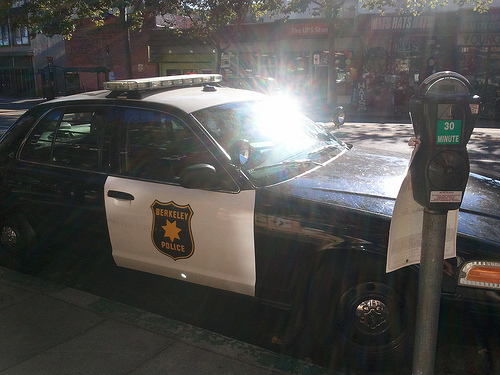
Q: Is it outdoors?
A: Yes, it is outdoors.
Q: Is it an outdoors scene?
A: Yes, it is outdoors.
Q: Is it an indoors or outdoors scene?
A: It is outdoors.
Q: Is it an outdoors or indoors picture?
A: It is outdoors.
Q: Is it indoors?
A: No, it is outdoors.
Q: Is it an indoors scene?
A: No, it is outdoors.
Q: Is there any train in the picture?
A: No, there are no trains.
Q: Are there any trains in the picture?
A: No, there are no trains.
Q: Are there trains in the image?
A: No, there are no trains.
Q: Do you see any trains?
A: No, there are no trains.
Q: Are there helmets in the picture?
A: No, there are no helmets.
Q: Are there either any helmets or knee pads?
A: No, there are no helmets or knee pads.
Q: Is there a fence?
A: No, there are no fences.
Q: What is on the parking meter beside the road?
A: The sign is on the parking meter.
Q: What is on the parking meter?
A: The sign is on the parking meter.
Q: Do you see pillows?
A: No, there are no pillows.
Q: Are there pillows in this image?
A: No, there are no pillows.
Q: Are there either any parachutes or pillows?
A: No, there are no pillows or parachutes.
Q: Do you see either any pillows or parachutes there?
A: No, there are no pillows or parachutes.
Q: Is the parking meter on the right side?
A: Yes, the parking meter is on the right of the image.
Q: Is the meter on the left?
A: No, the meter is on the right of the image.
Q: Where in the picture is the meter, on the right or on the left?
A: The meter is on the right of the image.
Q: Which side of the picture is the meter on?
A: The meter is on the right of the image.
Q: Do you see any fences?
A: No, there are no fences.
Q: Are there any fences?
A: No, there are no fences.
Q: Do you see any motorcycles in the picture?
A: No, there are no motorcycles.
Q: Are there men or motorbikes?
A: No, there are no motorbikes or men.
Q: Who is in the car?
A: The police officer is in the car.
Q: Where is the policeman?
A: The policeman is in the car.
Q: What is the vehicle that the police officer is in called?
A: The vehicle is a car.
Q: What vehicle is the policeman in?
A: The police officer is in the car.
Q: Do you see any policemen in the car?
A: Yes, there is a policeman in the car.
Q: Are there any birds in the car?
A: No, there is a policeman in the car.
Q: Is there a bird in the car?
A: No, there is a policeman in the car.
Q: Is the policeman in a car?
A: Yes, the policeman is in a car.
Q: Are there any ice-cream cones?
A: No, there are no ice-cream cones.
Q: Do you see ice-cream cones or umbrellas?
A: No, there are no ice-cream cones or umbrellas.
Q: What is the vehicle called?
A: The vehicle is a car.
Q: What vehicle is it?
A: The vehicle is a car.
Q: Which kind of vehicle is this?
A: This is a car.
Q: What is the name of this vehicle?
A: This is a car.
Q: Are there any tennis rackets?
A: No, there are no tennis rackets.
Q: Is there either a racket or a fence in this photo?
A: No, there are no rackets or fences.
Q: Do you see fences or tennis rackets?
A: No, there are no tennis rackets or fences.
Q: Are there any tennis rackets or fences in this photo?
A: No, there are no tennis rackets or fences.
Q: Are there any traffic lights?
A: No, there are no traffic lights.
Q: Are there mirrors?
A: Yes, there is a mirror.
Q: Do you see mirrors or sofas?
A: Yes, there is a mirror.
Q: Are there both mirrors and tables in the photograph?
A: No, there is a mirror but no tables.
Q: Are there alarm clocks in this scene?
A: No, there are no alarm clocks.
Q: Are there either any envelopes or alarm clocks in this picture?
A: No, there are no alarm clocks or envelopes.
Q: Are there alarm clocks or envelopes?
A: No, there are no alarm clocks or envelopes.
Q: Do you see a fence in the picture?
A: No, there are no fences.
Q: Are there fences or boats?
A: No, there are no fences or boats.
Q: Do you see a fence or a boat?
A: No, there are no fences or boats.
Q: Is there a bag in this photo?
A: No, there are no bags.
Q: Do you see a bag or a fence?
A: No, there are no bags or fences.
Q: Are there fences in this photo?
A: No, there are no fences.